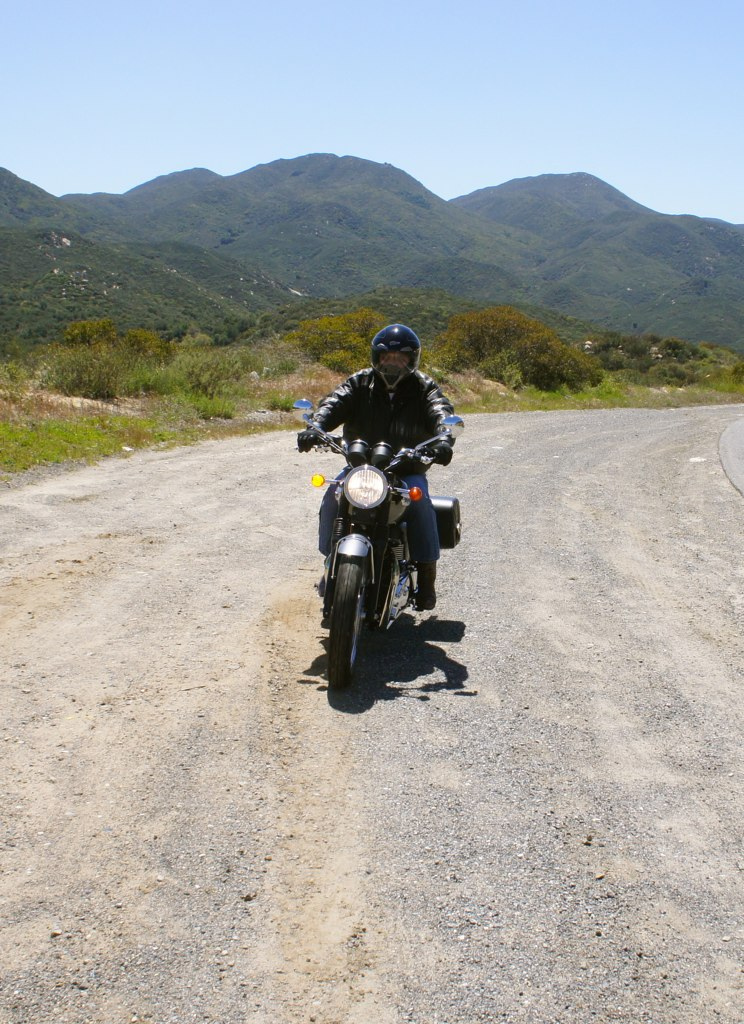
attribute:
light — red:
[408, 485, 421, 499]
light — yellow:
[312, 471, 324, 487]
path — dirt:
[1, 401, 742, 1021]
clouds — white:
[597, 119, 684, 173]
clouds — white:
[151, 46, 218, 98]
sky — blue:
[0, 0, 742, 227]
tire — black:
[327, 556, 362, 704]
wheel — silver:
[350, 583, 363, 669]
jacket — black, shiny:
[297, 367, 456, 480]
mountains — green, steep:
[0, 164, 742, 357]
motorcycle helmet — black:
[358, 315, 425, 363]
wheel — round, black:
[315, 552, 396, 719]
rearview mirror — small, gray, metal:
[437, 404, 468, 440]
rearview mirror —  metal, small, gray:
[294, 396, 319, 429]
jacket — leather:
[310, 372, 452, 486]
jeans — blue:
[314, 461, 435, 604]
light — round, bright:
[342, 463, 389, 507]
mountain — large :
[6, 117, 452, 329]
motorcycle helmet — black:
[363, 311, 429, 388]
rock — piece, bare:
[55, 229, 73, 250]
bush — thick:
[438, 294, 592, 377]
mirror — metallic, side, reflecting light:
[286, 393, 326, 436]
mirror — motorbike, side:
[432, 411, 468, 446]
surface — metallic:
[434, 409, 469, 440]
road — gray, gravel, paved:
[9, 411, 721, 1015]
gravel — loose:
[399, 795, 585, 915]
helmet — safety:
[362, 320, 426, 368]